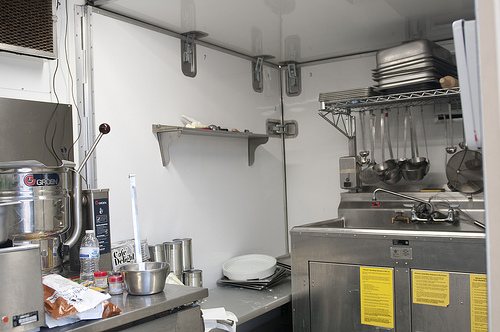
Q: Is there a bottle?
A: Yes, there is a bottle.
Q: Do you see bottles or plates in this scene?
A: Yes, there is a bottle.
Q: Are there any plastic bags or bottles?
A: Yes, there is a plastic bottle.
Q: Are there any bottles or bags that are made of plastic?
A: Yes, the bottle is made of plastic.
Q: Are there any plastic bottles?
A: Yes, there is a bottle that is made of plastic.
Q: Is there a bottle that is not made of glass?
A: Yes, there is a bottle that is made of plastic.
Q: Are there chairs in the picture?
A: No, there are no chairs.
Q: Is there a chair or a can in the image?
A: No, there are no chairs or cans.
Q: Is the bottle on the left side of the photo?
A: Yes, the bottle is on the left of the image.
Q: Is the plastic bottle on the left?
A: Yes, the bottle is on the left of the image.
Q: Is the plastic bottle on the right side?
A: No, the bottle is on the left of the image.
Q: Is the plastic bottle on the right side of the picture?
A: No, the bottle is on the left of the image.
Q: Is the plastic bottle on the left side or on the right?
A: The bottle is on the left of the image.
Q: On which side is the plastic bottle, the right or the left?
A: The bottle is on the left of the image.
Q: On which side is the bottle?
A: The bottle is on the left of the image.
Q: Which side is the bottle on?
A: The bottle is on the left of the image.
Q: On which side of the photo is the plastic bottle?
A: The bottle is on the left of the image.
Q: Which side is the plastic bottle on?
A: The bottle is on the left of the image.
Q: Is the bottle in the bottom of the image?
A: Yes, the bottle is in the bottom of the image.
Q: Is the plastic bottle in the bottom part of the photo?
A: Yes, the bottle is in the bottom of the image.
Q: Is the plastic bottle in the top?
A: No, the bottle is in the bottom of the image.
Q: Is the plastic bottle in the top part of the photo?
A: No, the bottle is in the bottom of the image.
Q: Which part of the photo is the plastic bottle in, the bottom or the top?
A: The bottle is in the bottom of the image.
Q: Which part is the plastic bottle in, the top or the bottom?
A: The bottle is in the bottom of the image.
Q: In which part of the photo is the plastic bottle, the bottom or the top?
A: The bottle is in the bottom of the image.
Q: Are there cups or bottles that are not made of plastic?
A: No, there is a bottle but it is made of plastic.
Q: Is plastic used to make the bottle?
A: Yes, the bottle is made of plastic.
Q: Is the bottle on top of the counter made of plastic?
A: Yes, the bottle is made of plastic.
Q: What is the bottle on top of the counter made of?
A: The bottle is made of plastic.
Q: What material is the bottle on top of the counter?
A: The bottle is made of plastic.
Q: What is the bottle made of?
A: The bottle is made of plastic.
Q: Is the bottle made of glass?
A: No, the bottle is made of plastic.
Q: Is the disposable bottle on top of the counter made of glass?
A: No, the bottle is made of plastic.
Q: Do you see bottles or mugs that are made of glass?
A: No, there is a bottle but it is made of plastic.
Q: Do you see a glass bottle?
A: No, there is a bottle but it is made of plastic.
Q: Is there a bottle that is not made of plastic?
A: No, there is a bottle but it is made of plastic.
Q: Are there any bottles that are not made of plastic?
A: No, there is a bottle but it is made of plastic.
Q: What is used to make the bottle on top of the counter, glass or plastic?
A: The bottle is made of plastic.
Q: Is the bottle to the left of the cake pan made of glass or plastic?
A: The bottle is made of plastic.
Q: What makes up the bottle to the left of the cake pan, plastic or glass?
A: The bottle is made of plastic.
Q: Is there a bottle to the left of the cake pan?
A: Yes, there is a bottle to the left of the cake pan.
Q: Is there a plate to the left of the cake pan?
A: No, there is a bottle to the left of the cake pan.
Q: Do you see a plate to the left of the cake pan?
A: No, there is a bottle to the left of the cake pan.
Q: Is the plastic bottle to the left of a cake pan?
A: Yes, the bottle is to the left of a cake pan.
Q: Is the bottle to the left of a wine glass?
A: No, the bottle is to the left of a cake pan.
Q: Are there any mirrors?
A: No, there are no mirrors.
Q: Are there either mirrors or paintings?
A: No, there are no mirrors or paintings.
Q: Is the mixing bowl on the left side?
A: Yes, the mixing bowl is on the left of the image.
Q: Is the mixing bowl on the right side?
A: No, the mixing bowl is on the left of the image.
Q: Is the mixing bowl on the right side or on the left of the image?
A: The mixing bowl is on the left of the image.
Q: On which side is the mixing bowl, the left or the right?
A: The mixing bowl is on the left of the image.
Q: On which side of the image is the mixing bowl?
A: The mixing bowl is on the left of the image.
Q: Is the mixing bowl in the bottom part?
A: Yes, the mixing bowl is in the bottom of the image.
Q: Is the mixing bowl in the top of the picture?
A: No, the mixing bowl is in the bottom of the image.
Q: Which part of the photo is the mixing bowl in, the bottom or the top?
A: The mixing bowl is in the bottom of the image.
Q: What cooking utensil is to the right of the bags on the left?
A: The cooking utensil is a mixing bowl.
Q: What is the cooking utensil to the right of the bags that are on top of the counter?
A: The cooking utensil is a mixing bowl.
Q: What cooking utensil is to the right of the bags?
A: The cooking utensil is a mixing bowl.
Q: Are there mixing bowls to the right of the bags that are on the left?
A: Yes, there is a mixing bowl to the right of the bags.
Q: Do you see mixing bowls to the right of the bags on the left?
A: Yes, there is a mixing bowl to the right of the bags.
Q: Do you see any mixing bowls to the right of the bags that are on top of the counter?
A: Yes, there is a mixing bowl to the right of the bags.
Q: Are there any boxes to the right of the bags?
A: No, there is a mixing bowl to the right of the bags.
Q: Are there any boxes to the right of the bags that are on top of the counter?
A: No, there is a mixing bowl to the right of the bags.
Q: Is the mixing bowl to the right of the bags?
A: Yes, the mixing bowl is to the right of the bags.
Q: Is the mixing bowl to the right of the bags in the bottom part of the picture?
A: Yes, the mixing bowl is to the right of the bags.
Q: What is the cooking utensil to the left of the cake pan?
A: The cooking utensil is a mixing bowl.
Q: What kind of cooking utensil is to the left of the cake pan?
A: The cooking utensil is a mixing bowl.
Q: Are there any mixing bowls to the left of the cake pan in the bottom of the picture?
A: Yes, there is a mixing bowl to the left of the cake pan.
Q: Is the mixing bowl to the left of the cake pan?
A: Yes, the mixing bowl is to the left of the cake pan.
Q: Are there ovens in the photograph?
A: No, there are no ovens.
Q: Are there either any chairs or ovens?
A: No, there are no ovens or chairs.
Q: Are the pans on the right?
A: Yes, the pans are on the right of the image.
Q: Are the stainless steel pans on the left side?
A: No, the pans are on the right of the image.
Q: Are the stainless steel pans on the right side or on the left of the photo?
A: The pans are on the right of the image.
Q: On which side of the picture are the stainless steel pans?
A: The pans are on the right of the image.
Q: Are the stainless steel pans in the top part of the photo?
A: Yes, the pans are in the top of the image.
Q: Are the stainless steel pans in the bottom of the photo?
A: No, the pans are in the top of the image.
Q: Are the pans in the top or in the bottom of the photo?
A: The pans are in the top of the image.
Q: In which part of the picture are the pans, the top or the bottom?
A: The pans are in the top of the image.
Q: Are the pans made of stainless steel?
A: Yes, the pans are made of stainless steel.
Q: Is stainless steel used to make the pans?
A: Yes, the pans are made of stainless steel.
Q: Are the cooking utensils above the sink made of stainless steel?
A: Yes, the pans are made of stainless steel.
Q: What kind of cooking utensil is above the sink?
A: The cooking utensils are pans.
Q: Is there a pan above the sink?
A: Yes, there are pans above the sink.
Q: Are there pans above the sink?
A: Yes, there are pans above the sink.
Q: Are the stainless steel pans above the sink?
A: Yes, the pans are above the sink.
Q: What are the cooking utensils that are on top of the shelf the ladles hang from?
A: The cooking utensils are pans.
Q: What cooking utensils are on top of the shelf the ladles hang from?
A: The cooking utensils are pans.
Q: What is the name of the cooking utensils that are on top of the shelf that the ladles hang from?
A: The cooking utensils are pans.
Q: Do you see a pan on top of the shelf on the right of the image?
A: Yes, there are pans on top of the shelf.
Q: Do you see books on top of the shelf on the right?
A: No, there are pans on top of the shelf.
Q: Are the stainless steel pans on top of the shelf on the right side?
A: Yes, the pans are on top of the shelf.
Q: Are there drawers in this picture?
A: No, there are no drawers.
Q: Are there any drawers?
A: No, there are no drawers.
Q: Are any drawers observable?
A: No, there are no drawers.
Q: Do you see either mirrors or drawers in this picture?
A: No, there are no drawers or mirrors.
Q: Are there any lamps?
A: No, there are no lamps.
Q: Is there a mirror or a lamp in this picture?
A: No, there are no lamps or mirrors.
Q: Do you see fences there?
A: No, there are no fences.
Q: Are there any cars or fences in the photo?
A: No, there are no fences or cars.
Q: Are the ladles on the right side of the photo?
A: Yes, the ladles are on the right of the image.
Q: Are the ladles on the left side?
A: No, the ladles are on the right of the image.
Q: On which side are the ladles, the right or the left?
A: The ladles are on the right of the image.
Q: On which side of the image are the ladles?
A: The ladles are on the right of the image.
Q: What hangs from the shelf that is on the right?
A: The ladles hang from the shelf.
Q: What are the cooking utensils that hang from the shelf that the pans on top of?
A: The cooking utensils are ladles.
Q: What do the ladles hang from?
A: The ladles hang from the shelf.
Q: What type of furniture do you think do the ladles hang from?
A: The ladles hang from the shelf.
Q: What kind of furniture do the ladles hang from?
A: The ladles hang from the shelf.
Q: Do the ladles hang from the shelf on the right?
A: Yes, the ladles hang from the shelf.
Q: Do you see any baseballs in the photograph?
A: No, there are no baseballs.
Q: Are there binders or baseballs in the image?
A: No, there are no baseballs or binders.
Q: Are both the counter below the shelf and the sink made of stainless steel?
A: Yes, both the counter and the sink are made of stainless steel.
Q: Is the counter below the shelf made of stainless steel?
A: Yes, the counter is made of stainless steel.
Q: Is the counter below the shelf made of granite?
A: No, the counter is made of stainless steel.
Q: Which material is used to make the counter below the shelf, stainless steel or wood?
A: The counter is made of stainless steel.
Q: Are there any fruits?
A: No, there are no fruits.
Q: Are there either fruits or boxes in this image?
A: No, there are no fruits or boxes.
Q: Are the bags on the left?
A: Yes, the bags are on the left of the image.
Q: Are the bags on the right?
A: No, the bags are on the left of the image.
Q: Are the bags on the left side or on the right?
A: The bags are on the left of the image.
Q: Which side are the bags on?
A: The bags are on the left of the image.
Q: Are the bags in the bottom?
A: Yes, the bags are in the bottom of the image.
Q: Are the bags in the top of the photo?
A: No, the bags are in the bottom of the image.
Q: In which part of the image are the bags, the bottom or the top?
A: The bags are in the bottom of the image.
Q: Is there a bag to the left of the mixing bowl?
A: Yes, there are bags to the left of the mixing bowl.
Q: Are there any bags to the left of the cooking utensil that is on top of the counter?
A: Yes, there are bags to the left of the mixing bowl.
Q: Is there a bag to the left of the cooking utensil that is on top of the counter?
A: Yes, there are bags to the left of the mixing bowl.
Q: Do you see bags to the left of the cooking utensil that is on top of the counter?
A: Yes, there are bags to the left of the mixing bowl.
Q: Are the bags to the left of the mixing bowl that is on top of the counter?
A: Yes, the bags are to the left of the mixing bowl.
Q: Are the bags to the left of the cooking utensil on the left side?
A: Yes, the bags are to the left of the mixing bowl.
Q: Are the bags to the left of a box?
A: No, the bags are to the left of the mixing bowl.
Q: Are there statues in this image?
A: No, there are no statues.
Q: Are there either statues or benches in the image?
A: No, there are no statues or benches.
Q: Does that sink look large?
A: Yes, the sink is large.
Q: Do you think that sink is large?
A: Yes, the sink is large.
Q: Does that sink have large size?
A: Yes, the sink is large.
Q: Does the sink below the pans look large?
A: Yes, the sink is large.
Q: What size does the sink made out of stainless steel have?
A: The sink has large size.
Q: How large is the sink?
A: The sink is large.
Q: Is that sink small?
A: No, the sink is large.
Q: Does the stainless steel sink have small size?
A: No, the sink is large.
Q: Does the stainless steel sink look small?
A: No, the sink is large.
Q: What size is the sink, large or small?
A: The sink is large.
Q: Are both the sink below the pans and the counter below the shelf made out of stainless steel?
A: Yes, both the sink and the counter are made of stainless steel.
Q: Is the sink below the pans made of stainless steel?
A: Yes, the sink is made of stainless steel.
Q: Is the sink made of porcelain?
A: No, the sink is made of stainless steel.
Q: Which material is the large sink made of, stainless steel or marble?
A: The sink is made of stainless steel.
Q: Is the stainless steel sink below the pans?
A: Yes, the sink is below the pans.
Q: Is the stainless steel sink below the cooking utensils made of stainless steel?
A: Yes, the sink is below the pans.